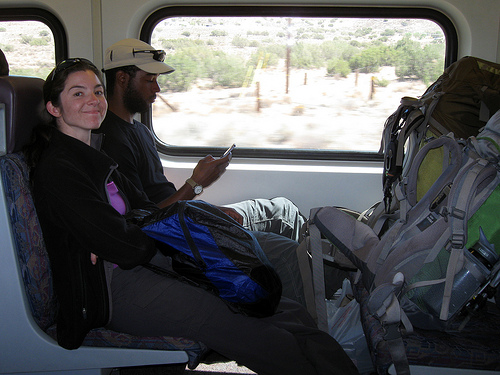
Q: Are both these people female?
A: No, they are both male and female.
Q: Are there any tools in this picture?
A: No, there are no tools.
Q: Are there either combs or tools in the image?
A: No, there are no tools or combs.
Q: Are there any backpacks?
A: Yes, there is a backpack.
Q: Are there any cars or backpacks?
A: Yes, there is a backpack.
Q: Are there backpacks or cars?
A: Yes, there is a backpack.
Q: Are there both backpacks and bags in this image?
A: Yes, there are both a backpack and a bag.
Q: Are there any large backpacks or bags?
A: Yes, there is a large backpack.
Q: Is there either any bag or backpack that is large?
A: Yes, the backpack is large.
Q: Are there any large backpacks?
A: Yes, there is a large backpack.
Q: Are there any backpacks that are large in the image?
A: Yes, there is a large backpack.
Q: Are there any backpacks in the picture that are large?
A: Yes, there is a backpack that is large.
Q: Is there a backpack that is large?
A: Yes, there is a backpack that is large.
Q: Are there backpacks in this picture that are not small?
A: Yes, there is a large backpack.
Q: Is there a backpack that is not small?
A: Yes, there is a large backpack.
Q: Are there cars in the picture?
A: No, there are no cars.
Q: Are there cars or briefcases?
A: No, there are no cars or briefcases.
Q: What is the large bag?
A: The bag is a backpack.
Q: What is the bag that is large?
A: The bag is a backpack.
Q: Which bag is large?
A: The bag is a backpack.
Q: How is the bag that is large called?
A: The bag is a backpack.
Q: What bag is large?
A: The bag is a backpack.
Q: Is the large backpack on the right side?
A: Yes, the backpack is on the right of the image.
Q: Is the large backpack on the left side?
A: No, the backpack is on the right of the image.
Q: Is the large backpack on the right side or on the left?
A: The backpack is on the right of the image.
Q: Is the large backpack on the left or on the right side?
A: The backpack is on the right of the image.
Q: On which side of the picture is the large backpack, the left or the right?
A: The backpack is on the right of the image.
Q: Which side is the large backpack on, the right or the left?
A: The backpack is on the right of the image.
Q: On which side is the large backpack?
A: The backpack is on the right of the image.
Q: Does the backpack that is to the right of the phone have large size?
A: Yes, the backpack is large.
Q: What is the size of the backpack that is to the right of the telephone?
A: The backpack is large.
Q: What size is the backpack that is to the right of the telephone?
A: The backpack is large.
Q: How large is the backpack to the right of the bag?
A: The backpack is large.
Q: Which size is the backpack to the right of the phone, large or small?
A: The backpack is large.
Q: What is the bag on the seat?
A: The bag is a backpack.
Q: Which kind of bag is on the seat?
A: The bag is a backpack.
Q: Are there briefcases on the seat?
A: No, there is a backpack on the seat.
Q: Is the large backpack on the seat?
A: Yes, the backpack is on the seat.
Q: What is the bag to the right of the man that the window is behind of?
A: The bag is a backpack.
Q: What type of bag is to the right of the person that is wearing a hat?
A: The bag is a backpack.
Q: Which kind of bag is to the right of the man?
A: The bag is a backpack.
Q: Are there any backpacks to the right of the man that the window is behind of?
A: Yes, there is a backpack to the right of the man.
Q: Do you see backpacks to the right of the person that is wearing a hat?
A: Yes, there is a backpack to the right of the man.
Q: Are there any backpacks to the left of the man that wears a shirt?
A: No, the backpack is to the right of the man.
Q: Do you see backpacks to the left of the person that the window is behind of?
A: No, the backpack is to the right of the man.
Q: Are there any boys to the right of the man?
A: No, there is a backpack to the right of the man.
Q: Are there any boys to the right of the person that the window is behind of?
A: No, there is a backpack to the right of the man.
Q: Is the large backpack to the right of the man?
A: Yes, the backpack is to the right of the man.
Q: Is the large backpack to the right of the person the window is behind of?
A: Yes, the backpack is to the right of the man.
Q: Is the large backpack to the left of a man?
A: No, the backpack is to the right of a man.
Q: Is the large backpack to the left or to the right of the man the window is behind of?
A: The backpack is to the right of the man.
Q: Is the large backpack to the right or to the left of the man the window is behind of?
A: The backpack is to the right of the man.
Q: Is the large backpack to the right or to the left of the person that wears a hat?
A: The backpack is to the right of the man.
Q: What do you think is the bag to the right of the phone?
A: The bag is a backpack.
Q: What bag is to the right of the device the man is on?
A: The bag is a backpack.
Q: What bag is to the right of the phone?
A: The bag is a backpack.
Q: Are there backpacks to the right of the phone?
A: Yes, there is a backpack to the right of the phone.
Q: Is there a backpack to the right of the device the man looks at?
A: Yes, there is a backpack to the right of the phone.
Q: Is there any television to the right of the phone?
A: No, there is a backpack to the right of the phone.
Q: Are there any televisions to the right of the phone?
A: No, there is a backpack to the right of the phone.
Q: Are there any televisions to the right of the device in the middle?
A: No, there is a backpack to the right of the phone.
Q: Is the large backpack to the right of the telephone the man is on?
A: Yes, the backpack is to the right of the telephone.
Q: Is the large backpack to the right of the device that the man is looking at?
A: Yes, the backpack is to the right of the telephone.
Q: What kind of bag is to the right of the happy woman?
A: The bag is a backpack.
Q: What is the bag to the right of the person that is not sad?
A: The bag is a backpack.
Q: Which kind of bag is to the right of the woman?
A: The bag is a backpack.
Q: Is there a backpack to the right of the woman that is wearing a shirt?
A: Yes, there is a backpack to the right of the woman.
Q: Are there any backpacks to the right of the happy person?
A: Yes, there is a backpack to the right of the woman.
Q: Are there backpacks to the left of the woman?
A: No, the backpack is to the right of the woman.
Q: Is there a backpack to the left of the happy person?
A: No, the backpack is to the right of the woman.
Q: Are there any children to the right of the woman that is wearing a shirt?
A: No, there is a backpack to the right of the woman.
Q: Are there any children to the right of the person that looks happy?
A: No, there is a backpack to the right of the woman.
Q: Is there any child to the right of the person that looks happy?
A: No, there is a backpack to the right of the woman.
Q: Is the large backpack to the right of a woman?
A: Yes, the backpack is to the right of a woman.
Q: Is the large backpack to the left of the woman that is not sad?
A: No, the backpack is to the right of the woman.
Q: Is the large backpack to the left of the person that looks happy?
A: No, the backpack is to the right of the woman.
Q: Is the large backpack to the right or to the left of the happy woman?
A: The backpack is to the right of the woman.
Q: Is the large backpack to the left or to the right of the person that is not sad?
A: The backpack is to the right of the woman.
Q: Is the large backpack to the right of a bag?
A: Yes, the backpack is to the right of a bag.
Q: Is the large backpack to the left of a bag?
A: No, the backpack is to the right of a bag.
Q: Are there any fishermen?
A: No, there are no fishermen.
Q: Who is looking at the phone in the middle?
A: The man is looking at the phone.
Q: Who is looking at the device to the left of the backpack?
A: The man is looking at the phone.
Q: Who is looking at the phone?
A: The man is looking at the phone.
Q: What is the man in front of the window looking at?
A: The man is looking at the phone.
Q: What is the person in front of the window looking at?
A: The man is looking at the phone.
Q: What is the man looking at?
A: The man is looking at the phone.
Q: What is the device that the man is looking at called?
A: The device is a phone.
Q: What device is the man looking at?
A: The man is looking at the phone.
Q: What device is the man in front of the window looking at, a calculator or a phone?
A: The man is looking at a phone.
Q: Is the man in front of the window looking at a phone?
A: Yes, the man is looking at a phone.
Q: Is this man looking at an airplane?
A: No, the man is looking at a phone.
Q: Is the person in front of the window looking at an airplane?
A: No, the man is looking at a phone.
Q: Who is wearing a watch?
A: The man is wearing a watch.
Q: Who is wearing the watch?
A: The man is wearing a watch.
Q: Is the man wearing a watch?
A: Yes, the man is wearing a watch.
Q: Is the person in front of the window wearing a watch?
A: Yes, the man is wearing a watch.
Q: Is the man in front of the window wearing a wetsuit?
A: No, the man is wearing a watch.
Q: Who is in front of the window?
A: The man is in front of the window.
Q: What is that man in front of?
A: The man is in front of the window.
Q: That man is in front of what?
A: The man is in front of the window.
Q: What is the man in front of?
A: The man is in front of the window.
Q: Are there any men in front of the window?
A: Yes, there is a man in front of the window.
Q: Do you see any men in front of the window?
A: Yes, there is a man in front of the window.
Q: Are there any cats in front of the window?
A: No, there is a man in front of the window.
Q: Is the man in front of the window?
A: Yes, the man is in front of the window.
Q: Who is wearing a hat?
A: The man is wearing a hat.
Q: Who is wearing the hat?
A: The man is wearing a hat.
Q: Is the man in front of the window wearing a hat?
A: Yes, the man is wearing a hat.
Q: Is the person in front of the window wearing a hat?
A: Yes, the man is wearing a hat.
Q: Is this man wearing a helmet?
A: No, the man is wearing a hat.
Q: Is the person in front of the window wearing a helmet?
A: No, the man is wearing a hat.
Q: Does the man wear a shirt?
A: Yes, the man wears a shirt.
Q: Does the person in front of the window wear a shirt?
A: Yes, the man wears a shirt.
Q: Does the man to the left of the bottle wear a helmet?
A: No, the man wears a shirt.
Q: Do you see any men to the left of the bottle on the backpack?
A: Yes, there is a man to the left of the bottle.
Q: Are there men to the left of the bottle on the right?
A: Yes, there is a man to the left of the bottle.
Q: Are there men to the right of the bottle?
A: No, the man is to the left of the bottle.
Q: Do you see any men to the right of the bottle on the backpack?
A: No, the man is to the left of the bottle.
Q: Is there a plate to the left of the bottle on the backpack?
A: No, there is a man to the left of the bottle.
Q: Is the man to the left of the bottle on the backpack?
A: Yes, the man is to the left of the bottle.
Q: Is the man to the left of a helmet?
A: No, the man is to the left of the bottle.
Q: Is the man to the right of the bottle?
A: No, the man is to the left of the bottle.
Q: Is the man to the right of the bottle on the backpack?
A: No, the man is to the left of the bottle.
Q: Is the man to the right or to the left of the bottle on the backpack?
A: The man is to the left of the bottle.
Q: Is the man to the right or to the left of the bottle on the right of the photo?
A: The man is to the left of the bottle.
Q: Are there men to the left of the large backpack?
A: Yes, there is a man to the left of the backpack.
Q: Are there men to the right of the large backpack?
A: No, the man is to the left of the backpack.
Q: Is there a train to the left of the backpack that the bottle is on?
A: No, there is a man to the left of the backpack.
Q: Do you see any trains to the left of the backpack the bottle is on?
A: No, there is a man to the left of the backpack.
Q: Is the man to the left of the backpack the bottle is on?
A: Yes, the man is to the left of the backpack.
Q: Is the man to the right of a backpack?
A: No, the man is to the left of a backpack.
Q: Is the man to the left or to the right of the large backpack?
A: The man is to the left of the backpack.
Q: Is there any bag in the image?
A: Yes, there is a bag.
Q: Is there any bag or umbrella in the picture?
A: Yes, there is a bag.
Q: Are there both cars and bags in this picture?
A: No, there is a bag but no cars.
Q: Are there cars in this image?
A: No, there are no cars.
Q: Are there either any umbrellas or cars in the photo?
A: No, there are no cars or umbrellas.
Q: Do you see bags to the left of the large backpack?
A: Yes, there is a bag to the left of the backpack.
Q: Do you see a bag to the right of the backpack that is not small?
A: No, the bag is to the left of the backpack.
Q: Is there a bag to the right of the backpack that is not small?
A: No, the bag is to the left of the backpack.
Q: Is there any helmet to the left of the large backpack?
A: No, there is a bag to the left of the backpack.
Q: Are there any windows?
A: Yes, there is a window.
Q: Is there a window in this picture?
A: Yes, there is a window.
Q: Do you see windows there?
A: Yes, there is a window.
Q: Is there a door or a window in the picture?
A: Yes, there is a window.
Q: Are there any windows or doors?
A: Yes, there is a window.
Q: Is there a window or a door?
A: Yes, there is a window.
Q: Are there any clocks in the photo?
A: No, there are no clocks.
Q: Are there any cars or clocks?
A: No, there are no clocks or cars.